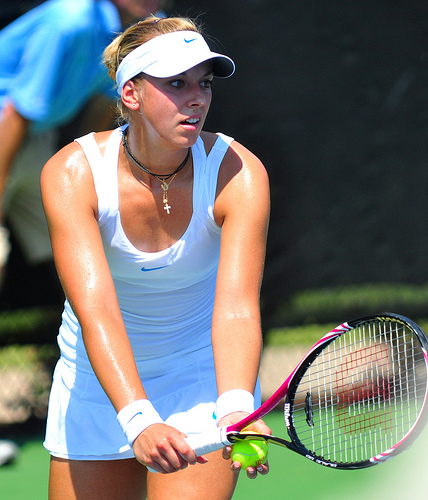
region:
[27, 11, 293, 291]
the woman is blonde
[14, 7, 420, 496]
woman wears white dress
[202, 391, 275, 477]
ball on a hand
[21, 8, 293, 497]
woman wears white hat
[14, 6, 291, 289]
woman has a necklace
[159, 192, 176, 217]
a cross hangs from necklace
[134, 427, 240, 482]
handle of racket is white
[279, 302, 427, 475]
head of racket is pink and black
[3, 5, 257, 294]
person behind tennis player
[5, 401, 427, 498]
floor of tennis court is green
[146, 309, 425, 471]
Woman holding a racket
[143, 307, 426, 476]
Woman is holding a racket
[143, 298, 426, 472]
Woman holding a tennis racket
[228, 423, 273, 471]
Woman holding a ball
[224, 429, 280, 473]
Woman is holding a ball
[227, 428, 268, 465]
Woman holding a tennis ball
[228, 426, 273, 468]
Woman is holding a tennis ball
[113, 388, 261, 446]
Woman wearing white sweatbands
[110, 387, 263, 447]
Woman is wearing white sweatbands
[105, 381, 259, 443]
white sweatbands on a womans wrists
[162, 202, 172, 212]
a cross on a woman's necklace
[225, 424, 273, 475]
a woman holding a tennis ball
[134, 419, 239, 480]
white grip tape on a tennis racket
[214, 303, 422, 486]
a red and black tennis racket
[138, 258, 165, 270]
blue logo on a woman's shirt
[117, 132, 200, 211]
several necklaces around a woman's neck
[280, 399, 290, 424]
white logo on the tennis racket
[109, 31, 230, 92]
white visor on a woman's head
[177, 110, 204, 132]
a woman's teeth in her mouth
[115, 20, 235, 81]
white and blue visor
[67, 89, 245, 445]
girl has white dress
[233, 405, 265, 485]
tennis ball in hand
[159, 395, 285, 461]
white grip on racket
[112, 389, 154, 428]
white and blue wristbands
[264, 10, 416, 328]
black fence behind girl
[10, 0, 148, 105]
judge has blue shirt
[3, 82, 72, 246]
judge has white shorts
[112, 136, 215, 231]
girl is wearing necklace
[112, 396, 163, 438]
wrist band on the tennis player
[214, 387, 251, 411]
wrist on the tennis player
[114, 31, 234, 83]
visor on the tennis player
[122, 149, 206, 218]
necklace on the tennis player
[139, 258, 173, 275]
logo on the shirt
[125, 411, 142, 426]
logo on the wrist band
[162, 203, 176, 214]
cross on the chain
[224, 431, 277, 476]
tennis ball in the player's hand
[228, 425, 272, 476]
tennis ball in the woman's hand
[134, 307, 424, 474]
racquet in the player's hand